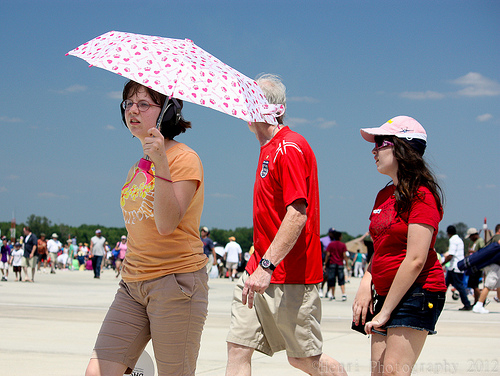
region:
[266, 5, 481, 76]
The sky is clear and blue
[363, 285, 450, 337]
The woman is wearing blue jean shorts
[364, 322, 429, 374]
The thighs on the woman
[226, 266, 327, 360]
The man is wearing khaki shorts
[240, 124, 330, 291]
The shirt is the color red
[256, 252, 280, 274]
The man is wearing a watch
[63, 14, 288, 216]
The woman is holding an umbrella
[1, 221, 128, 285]
The crowd of people on the ground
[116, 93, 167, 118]
The woman is wearing glasses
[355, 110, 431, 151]
The woman is wearing a hat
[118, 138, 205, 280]
an orange shirt on a woman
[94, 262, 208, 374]
light brown shorts on a woman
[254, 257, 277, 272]
a black watch on a man's wrist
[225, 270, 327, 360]
tan shorts on a man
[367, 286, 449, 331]
jean shorts on a girl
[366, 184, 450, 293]
a red shirt on a girl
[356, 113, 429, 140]
a cap on a girl's head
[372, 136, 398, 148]
sunglasses on a girl's face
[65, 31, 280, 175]
a white umbrella with pink hearts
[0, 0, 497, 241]
a blue sky with a few clouds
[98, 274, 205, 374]
a khaki short pant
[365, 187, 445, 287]
the t-shirt is red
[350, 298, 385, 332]
she is holding something black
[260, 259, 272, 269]
a black men wristwatch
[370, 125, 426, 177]
the head of the girl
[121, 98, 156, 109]
she is wearing eyeglasses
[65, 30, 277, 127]
a white and pink little hearts umbrella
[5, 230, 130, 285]
many people in the distance out of focus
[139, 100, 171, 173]
she is holding the umbrella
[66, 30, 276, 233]
a woman holding an umbrella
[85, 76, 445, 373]
three people walking on the beach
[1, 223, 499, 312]
a crowd of people on the beach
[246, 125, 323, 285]
man wearing a red shirt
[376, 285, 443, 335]
woman wearing short jeans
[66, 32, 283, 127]
a white and pink umbrella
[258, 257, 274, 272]
man wearing a black watch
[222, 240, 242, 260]
man wearing a white shirt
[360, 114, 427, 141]
woman wearing a pink cap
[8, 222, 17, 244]
a red and white tower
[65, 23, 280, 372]
a woman carrying a umbrella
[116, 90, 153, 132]
the face of a woman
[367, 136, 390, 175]
the face of a woman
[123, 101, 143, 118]
the nose of a woman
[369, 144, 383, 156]
the nose of a woman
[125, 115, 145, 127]
the mouth of a woman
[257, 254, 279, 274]
a watch on a wrist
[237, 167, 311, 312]
an arm of a man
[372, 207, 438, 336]
the arm of a woman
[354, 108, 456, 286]
a woman wearing a red shirt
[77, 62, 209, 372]
person walking on the sandy beach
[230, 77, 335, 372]
person walking on the sandy beach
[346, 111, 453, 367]
person walking on the sandy beach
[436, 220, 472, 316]
person walking on the sandy beach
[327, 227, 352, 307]
person walking on the sandy beach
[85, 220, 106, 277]
person walking on the sandy beach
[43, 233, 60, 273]
person walking on the sandy beach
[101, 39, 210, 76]
umbrella with pink hearts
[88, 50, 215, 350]
woman holding an umbrella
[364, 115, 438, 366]
woman in a red t-shirt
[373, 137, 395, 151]
sunglasses on woman's face